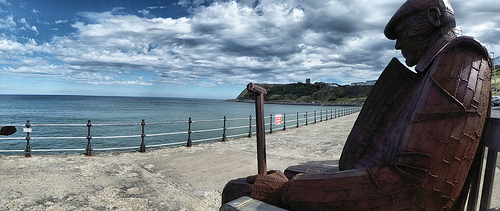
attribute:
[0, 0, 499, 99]
sky — cloudy, blue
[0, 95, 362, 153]
water — calm, large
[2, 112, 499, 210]
railing — metal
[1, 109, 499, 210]
walkway — concrete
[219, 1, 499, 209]
statue — seated, brown, bronze, male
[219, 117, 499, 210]
bench — bronze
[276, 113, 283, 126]
sign — red, white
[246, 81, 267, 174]
cane — brown, bronze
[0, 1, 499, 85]
clouds — puffy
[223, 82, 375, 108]
rocks — gray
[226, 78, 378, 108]
cliff — green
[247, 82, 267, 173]
stick — metal